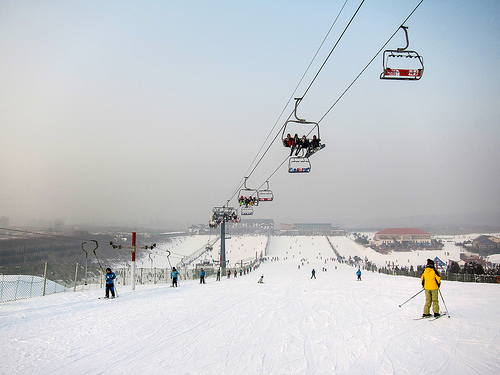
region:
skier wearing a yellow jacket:
[397, 257, 453, 321]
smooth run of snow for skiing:
[1, 234, 499, 373]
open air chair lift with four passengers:
[279, 95, 324, 159]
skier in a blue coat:
[93, 265, 123, 302]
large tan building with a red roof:
[371, 225, 433, 245]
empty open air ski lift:
[377, 23, 424, 80]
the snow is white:
[261, 300, 332, 337]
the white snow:
[218, 321, 294, 361]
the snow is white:
[205, 320, 288, 372]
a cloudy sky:
[356, 161, 416, 196]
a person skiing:
[412, 263, 450, 316]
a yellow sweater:
[423, 266, 441, 292]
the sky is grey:
[124, 153, 181, 195]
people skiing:
[307, 265, 317, 287]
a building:
[383, 223, 419, 235]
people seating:
[285, 132, 320, 144]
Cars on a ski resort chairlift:
[211, 124, 330, 220]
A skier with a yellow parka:
[417, 260, 445, 330]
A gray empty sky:
[71, 112, 166, 189]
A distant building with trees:
[378, 223, 436, 253]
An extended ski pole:
[398, 289, 423, 308]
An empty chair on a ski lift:
[378, 29, 429, 86]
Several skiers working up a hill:
[91, 258, 212, 307]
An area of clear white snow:
[243, 313, 352, 355]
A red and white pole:
[122, 226, 142, 291]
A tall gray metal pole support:
[218, 219, 230, 284]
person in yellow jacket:
[383, 253, 472, 338]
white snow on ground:
[294, 300, 385, 360]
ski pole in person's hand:
[379, 283, 426, 320]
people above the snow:
[260, 119, 335, 170]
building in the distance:
[350, 213, 439, 260]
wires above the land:
[238, 120, 305, 193]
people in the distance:
[264, 238, 347, 296]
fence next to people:
[25, 257, 88, 311]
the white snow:
[288, 301, 341, 351]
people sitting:
[283, 128, 328, 147]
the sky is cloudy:
[96, 104, 175, 154]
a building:
[378, 223, 433, 239]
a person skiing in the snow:
[308, 266, 322, 281]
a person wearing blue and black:
[166, 263, 181, 285]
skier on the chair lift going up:
[300, 130, 307, 152]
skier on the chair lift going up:
[292, 128, 302, 153]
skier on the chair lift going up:
[283, 130, 293, 150]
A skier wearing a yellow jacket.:
[418, 265, 440, 290]